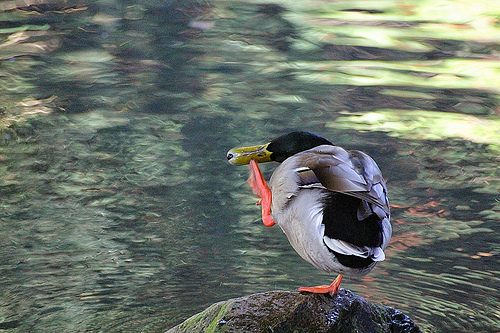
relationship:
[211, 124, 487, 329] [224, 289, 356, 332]
duck on rock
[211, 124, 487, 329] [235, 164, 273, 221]
duck has feet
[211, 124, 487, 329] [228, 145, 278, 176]
duck has beak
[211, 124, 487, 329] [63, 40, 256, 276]
duck near water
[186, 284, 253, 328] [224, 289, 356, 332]
part of stone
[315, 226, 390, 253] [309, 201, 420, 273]
wing of tail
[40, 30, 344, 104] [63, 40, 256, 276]
body of water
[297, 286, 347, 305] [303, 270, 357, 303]
part of leg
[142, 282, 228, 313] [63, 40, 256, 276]
waves in water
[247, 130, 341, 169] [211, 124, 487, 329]
head of duck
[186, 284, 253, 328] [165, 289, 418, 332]
part of rock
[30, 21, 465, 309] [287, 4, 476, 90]
photo during day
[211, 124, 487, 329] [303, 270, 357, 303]
duck has leg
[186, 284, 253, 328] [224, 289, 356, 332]
part of rock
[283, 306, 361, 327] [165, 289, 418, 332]
surface of rock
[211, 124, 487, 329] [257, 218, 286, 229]
duck has knee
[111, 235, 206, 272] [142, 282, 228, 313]
part of waves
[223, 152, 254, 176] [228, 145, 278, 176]
tip of beak